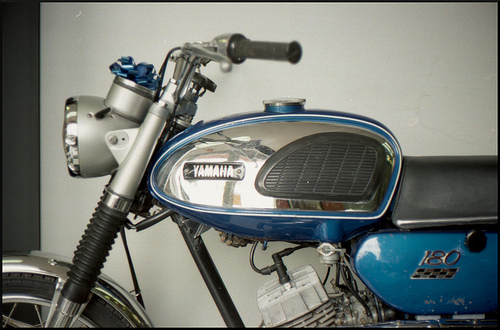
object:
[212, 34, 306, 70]
handles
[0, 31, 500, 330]
bike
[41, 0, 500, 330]
wall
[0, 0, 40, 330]
wall